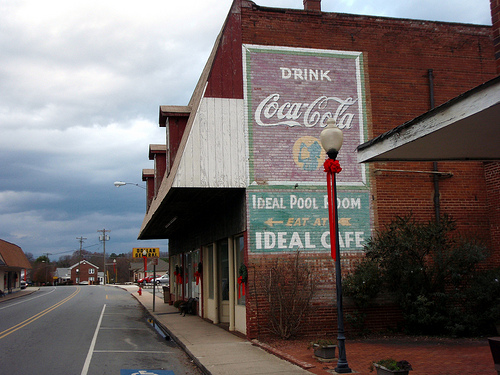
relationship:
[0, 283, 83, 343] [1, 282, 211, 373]
lines is on road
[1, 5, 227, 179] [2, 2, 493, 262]
clouds is in sky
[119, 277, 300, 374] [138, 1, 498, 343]
sidewalk is beside building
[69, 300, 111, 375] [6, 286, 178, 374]
line is in street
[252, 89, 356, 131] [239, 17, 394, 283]
coca-cola is on wall